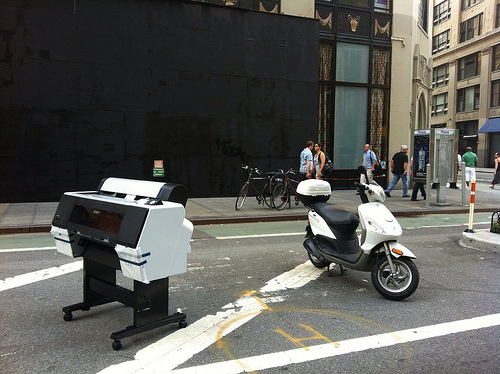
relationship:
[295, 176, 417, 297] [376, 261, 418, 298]
motorcycle has wheel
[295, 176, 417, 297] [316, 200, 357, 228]
motorcycle has seat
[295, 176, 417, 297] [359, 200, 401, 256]
motorcycle has guard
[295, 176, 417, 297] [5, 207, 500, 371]
motorcycle on road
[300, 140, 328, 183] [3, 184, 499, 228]
couple standing on sidewalk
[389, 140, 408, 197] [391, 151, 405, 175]
man wears t-shirt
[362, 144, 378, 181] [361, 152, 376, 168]
man in shirt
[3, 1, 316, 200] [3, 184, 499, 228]
wall near sidewalk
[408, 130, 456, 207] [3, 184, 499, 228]
phone on sidewalk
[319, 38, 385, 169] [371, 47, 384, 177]
window has curtains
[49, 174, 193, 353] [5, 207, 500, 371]
barbeque in road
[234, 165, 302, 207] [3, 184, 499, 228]
bicycles on sidewalk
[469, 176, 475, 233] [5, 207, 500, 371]
pole by road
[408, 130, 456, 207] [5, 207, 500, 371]
phone near road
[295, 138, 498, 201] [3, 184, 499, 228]
people on sidewalk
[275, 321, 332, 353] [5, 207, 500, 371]
h on road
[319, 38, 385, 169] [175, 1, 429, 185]
window on building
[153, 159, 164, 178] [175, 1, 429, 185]
sign on building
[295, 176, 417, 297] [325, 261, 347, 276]
motorcycle on kickstand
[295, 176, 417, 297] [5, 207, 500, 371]
motorcycle in road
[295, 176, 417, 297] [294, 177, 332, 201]
motorcycle has trunk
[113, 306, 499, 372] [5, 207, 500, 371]
line on road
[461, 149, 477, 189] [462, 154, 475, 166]
man wears shirt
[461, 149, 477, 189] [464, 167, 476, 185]
man wears pants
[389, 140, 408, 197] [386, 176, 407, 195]
man wears blue jeans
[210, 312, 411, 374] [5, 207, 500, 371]
circle on road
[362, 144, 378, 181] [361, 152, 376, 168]
man wears shirt